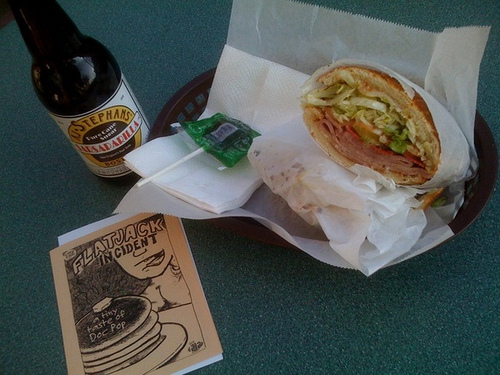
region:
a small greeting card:
[46, 217, 229, 374]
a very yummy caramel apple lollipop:
[142, 102, 242, 212]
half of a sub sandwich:
[300, 59, 454, 209]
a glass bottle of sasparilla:
[25, 34, 151, 187]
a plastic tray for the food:
[168, 52, 498, 259]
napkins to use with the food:
[163, 52, 271, 229]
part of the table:
[234, 242, 468, 374]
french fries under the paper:
[269, 132, 421, 269]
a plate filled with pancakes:
[71, 300, 170, 370]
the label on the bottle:
[42, 109, 152, 174]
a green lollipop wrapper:
[166, 105, 262, 177]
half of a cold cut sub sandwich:
[298, 51, 474, 193]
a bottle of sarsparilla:
[10, 17, 160, 186]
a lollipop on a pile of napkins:
[123, 39, 315, 224]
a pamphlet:
[48, 202, 225, 371]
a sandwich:
[243, 52, 477, 240]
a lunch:
[3, 0, 496, 372]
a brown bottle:
[3, 2, 161, 192]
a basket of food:
[145, 30, 499, 259]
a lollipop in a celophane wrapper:
[128, 113, 258, 196]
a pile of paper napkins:
[123, 42, 310, 218]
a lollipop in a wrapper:
[131, 109, 261, 192]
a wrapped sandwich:
[291, 58, 471, 188]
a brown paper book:
[47, 205, 227, 373]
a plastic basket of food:
[138, 48, 490, 242]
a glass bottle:
[6, 0, 157, 185]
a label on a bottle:
[41, 72, 157, 176]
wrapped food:
[248, 114, 426, 274]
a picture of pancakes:
[70, 294, 162, 373]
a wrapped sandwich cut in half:
[242, 43, 474, 274]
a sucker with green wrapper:
[134, 107, 256, 192]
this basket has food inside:
[128, 2, 498, 268]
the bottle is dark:
[10, 2, 155, 177]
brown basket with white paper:
[132, 19, 497, 249]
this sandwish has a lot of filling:
[295, 57, 477, 198]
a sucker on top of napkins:
[137, 23, 308, 236]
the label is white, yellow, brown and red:
[40, 89, 170, 184]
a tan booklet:
[42, 207, 225, 372]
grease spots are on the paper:
[253, 148, 324, 224]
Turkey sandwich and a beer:
[8, 4, 497, 258]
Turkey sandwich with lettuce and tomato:
[265, 22, 476, 247]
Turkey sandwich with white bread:
[301, 42, 496, 240]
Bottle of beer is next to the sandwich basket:
[0, 2, 152, 196]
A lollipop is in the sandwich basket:
[164, 88, 287, 216]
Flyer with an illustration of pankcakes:
[40, 218, 242, 373]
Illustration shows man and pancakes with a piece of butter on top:
[58, 207, 225, 373]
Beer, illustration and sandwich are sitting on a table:
[14, 10, 486, 356]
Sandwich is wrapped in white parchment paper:
[199, 22, 481, 276]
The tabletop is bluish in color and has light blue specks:
[217, 243, 489, 373]